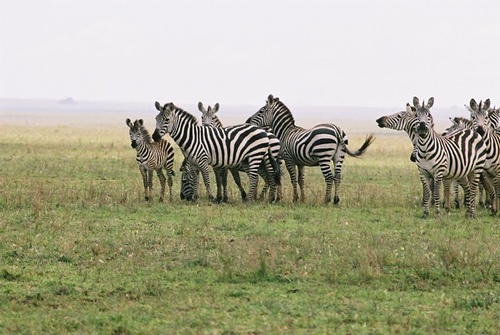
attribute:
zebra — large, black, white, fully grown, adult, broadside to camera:
[153, 101, 282, 203]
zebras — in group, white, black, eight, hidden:
[125, 91, 498, 219]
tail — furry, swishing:
[337, 130, 375, 157]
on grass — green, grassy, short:
[0, 99, 498, 334]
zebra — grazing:
[180, 158, 201, 203]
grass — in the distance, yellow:
[1, 100, 500, 160]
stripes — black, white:
[172, 112, 267, 163]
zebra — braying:
[376, 104, 415, 136]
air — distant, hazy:
[1, 1, 500, 131]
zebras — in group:
[374, 94, 500, 215]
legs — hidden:
[420, 170, 498, 205]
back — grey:
[327, 171, 342, 182]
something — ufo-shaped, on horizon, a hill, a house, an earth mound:
[51, 92, 88, 111]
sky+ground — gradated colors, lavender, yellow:
[0, 88, 500, 215]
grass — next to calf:
[114, 178, 180, 211]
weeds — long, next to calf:
[131, 184, 178, 204]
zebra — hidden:
[451, 115, 477, 136]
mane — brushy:
[453, 117, 472, 125]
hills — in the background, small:
[2, 93, 496, 126]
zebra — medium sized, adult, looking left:
[411, 96, 488, 213]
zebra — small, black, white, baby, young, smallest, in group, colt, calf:
[125, 116, 176, 201]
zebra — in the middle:
[246, 93, 376, 203]